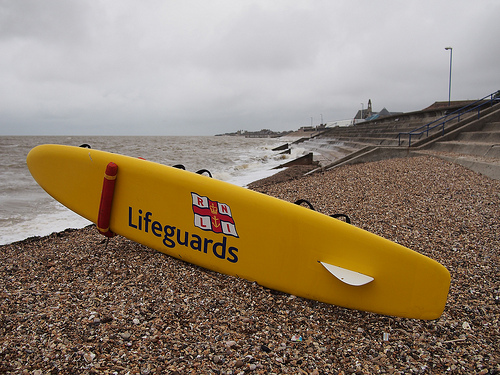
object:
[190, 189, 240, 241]
flag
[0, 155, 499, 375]
beach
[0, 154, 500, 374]
"rocky beach surface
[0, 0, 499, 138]
cloudy day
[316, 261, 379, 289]
fin on surf board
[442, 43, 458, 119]
light pole on stairs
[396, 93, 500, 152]
blue stair railings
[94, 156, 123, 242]
red surf board stand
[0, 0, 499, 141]
white clouds in sky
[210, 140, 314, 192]
white waves in ocean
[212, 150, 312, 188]
wave crash to shore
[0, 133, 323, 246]
rough brown waters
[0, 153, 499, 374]
stones on the sand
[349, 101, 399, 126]
house at a distance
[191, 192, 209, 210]
capital r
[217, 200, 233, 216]
capital n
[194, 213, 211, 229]
capital l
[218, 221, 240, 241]
capital i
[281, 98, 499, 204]
stairs leading up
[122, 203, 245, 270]
word lifeguards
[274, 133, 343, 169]
water leads stairs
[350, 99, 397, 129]
houses are visible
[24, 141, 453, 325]
board is visible